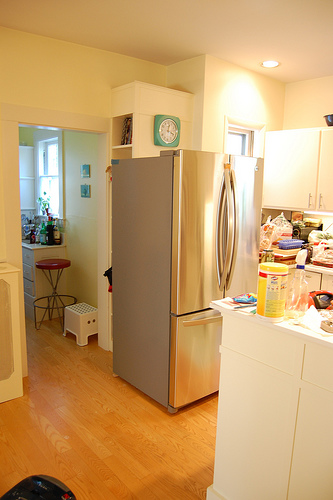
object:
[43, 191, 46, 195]
leaves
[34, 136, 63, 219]
window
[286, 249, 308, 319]
bottle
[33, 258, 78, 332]
stool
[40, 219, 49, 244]
bottle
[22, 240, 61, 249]
counter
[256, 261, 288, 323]
container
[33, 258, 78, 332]
bar stool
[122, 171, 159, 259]
stainless steel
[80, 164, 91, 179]
painting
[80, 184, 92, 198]
painting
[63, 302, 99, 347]
foot stool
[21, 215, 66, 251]
windowsill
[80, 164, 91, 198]
images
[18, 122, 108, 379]
doorway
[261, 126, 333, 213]
cabinets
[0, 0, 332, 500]
kitchen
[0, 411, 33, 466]
flooring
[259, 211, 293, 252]
bag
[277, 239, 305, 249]
plastic container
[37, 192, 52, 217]
green plant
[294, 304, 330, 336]
wipes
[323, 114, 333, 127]
bowl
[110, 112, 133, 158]
shelf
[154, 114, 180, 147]
framed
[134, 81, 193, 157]
wall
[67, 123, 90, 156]
wall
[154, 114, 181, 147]
clock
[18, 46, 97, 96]
wall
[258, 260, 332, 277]
counter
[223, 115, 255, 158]
window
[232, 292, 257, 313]
disinfecting wipes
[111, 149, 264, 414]
fridge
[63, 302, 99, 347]
step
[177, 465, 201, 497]
floors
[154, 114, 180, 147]
border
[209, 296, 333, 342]
counter top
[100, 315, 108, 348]
wall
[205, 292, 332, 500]
counter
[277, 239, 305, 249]
item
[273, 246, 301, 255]
item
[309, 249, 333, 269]
item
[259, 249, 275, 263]
item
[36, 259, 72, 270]
seat